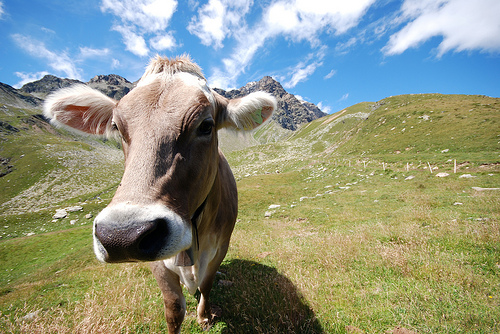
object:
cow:
[38, 50, 280, 334]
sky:
[1, 0, 500, 117]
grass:
[1, 135, 500, 331]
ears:
[39, 82, 121, 141]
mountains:
[0, 81, 52, 139]